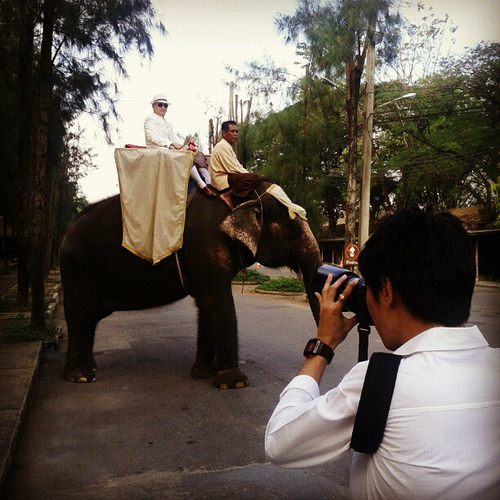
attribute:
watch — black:
[302, 338, 334, 362]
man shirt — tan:
[205, 111, 262, 203]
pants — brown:
[184, 155, 248, 222]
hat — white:
[137, 79, 183, 108]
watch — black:
[297, 337, 337, 365]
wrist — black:
[294, 335, 339, 387]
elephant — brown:
[54, 173, 334, 392]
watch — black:
[267, 329, 379, 372]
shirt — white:
[258, 323, 499, 498]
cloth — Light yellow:
[88, 150, 209, 248]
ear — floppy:
[213, 183, 281, 279]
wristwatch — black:
[275, 327, 350, 362]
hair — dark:
[219, 117, 238, 132]